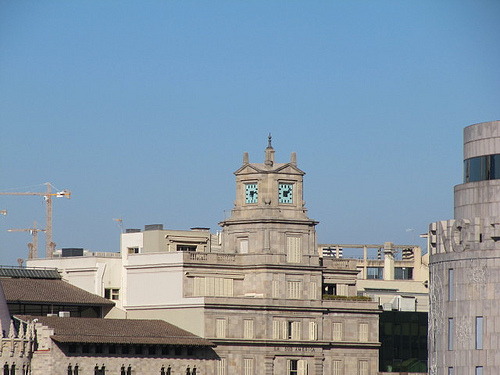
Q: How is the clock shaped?
A: As a square.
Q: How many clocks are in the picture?
A: Two.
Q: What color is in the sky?
A: Blue.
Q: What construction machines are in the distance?
A: Cranes.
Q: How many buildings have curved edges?
A: One.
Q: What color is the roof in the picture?
A: Brown.